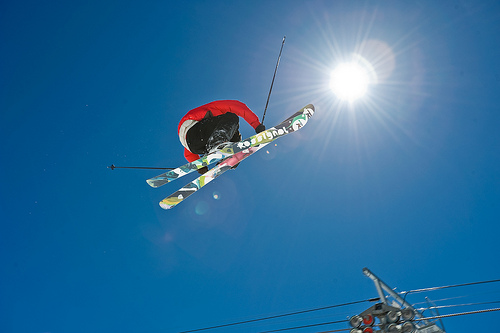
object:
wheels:
[361, 313, 376, 326]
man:
[177, 99, 265, 175]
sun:
[267, 1, 444, 166]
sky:
[306, 187, 499, 332]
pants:
[185, 111, 248, 155]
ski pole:
[261, 36, 286, 124]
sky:
[32, 11, 186, 132]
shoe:
[206, 141, 236, 154]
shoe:
[230, 161, 240, 169]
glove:
[254, 124, 266, 134]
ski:
[144, 113, 308, 189]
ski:
[158, 103, 315, 210]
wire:
[173, 279, 499, 332]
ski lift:
[346, 266, 448, 333]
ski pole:
[104, 163, 176, 171]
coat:
[177, 99, 262, 162]